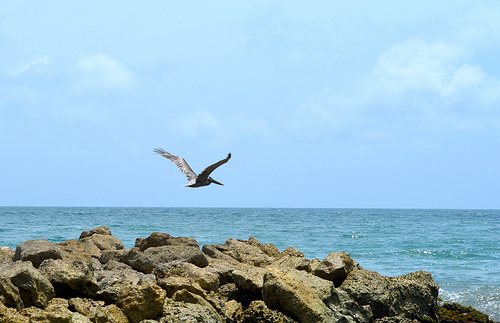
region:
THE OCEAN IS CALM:
[255, 212, 493, 269]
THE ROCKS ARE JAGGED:
[39, 237, 362, 320]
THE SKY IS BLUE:
[7, 131, 495, 195]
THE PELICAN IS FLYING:
[138, 141, 260, 193]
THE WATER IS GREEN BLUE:
[334, 211, 486, 271]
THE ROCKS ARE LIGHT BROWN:
[25, 247, 296, 320]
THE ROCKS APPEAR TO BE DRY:
[23, 242, 347, 319]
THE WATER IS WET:
[7, 207, 367, 226]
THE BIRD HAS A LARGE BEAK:
[206, 174, 223, 191]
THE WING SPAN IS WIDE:
[140, 141, 241, 182]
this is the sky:
[124, 12, 334, 70]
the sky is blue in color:
[232, 24, 304, 64]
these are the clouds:
[374, 47, 445, 93]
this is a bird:
[153, 145, 238, 190]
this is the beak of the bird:
[213, 179, 224, 186]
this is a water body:
[319, 204, 457, 244]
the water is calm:
[348, 209, 494, 246]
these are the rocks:
[73, 240, 288, 293]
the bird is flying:
[161, 149, 239, 189]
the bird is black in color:
[186, 167, 198, 185]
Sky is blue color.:
[80, 35, 356, 100]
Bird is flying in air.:
[155, 140, 251, 208]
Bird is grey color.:
[155, 140, 236, 195]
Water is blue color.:
[345, 216, 456, 251]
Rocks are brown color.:
[95, 245, 290, 311]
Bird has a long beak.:
[205, 170, 227, 193]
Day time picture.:
[23, 23, 493, 299]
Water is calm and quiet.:
[293, 210, 469, 255]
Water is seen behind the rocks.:
[28, 207, 470, 238]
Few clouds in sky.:
[33, 46, 458, 108]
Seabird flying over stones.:
[146, 139, 243, 199]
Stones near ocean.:
[1, 225, 496, 321]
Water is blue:
[0, 202, 497, 244]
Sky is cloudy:
[4, 6, 496, 148]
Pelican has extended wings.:
[146, 136, 236, 193]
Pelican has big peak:
[209, 176, 226, 188]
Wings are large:
[149, 139, 236, 179]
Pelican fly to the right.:
[148, 136, 241, 194]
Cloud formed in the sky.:
[16, 48, 147, 108]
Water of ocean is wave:
[280, 199, 496, 321]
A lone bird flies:
[130, 136, 250, 206]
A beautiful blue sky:
[60, 20, 445, 177]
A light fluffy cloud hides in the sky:
[335, 20, 480, 145]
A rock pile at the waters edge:
[25, 221, 360, 312]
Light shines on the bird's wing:
[145, 141, 202, 177]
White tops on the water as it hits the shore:
[417, 272, 482, 313]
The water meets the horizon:
[220, 177, 443, 233]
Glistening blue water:
[269, 211, 483, 247]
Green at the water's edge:
[425, 297, 486, 318]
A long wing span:
[148, 144, 232, 190]